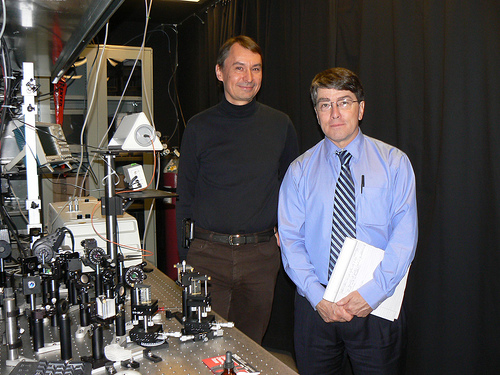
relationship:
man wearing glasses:
[277, 64, 419, 374] [309, 89, 356, 114]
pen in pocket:
[358, 174, 365, 191] [355, 184, 392, 229]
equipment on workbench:
[1, 0, 254, 371] [3, 255, 300, 374]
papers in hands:
[321, 237, 409, 322] [313, 288, 370, 324]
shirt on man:
[173, 86, 291, 291] [178, 36, 288, 340]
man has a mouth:
[277, 64, 419, 374] [314, 114, 355, 138]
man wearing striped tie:
[277, 64, 419, 374] [328, 148, 360, 278]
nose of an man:
[330, 105, 342, 119] [277, 64, 419, 374]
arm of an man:
[375, 152, 418, 294] [277, 64, 419, 374]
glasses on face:
[247, 74, 423, 366] [297, 71, 382, 146]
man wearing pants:
[171, 35, 285, 310] [182, 215, 275, 320]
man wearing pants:
[277, 64, 419, 374] [294, 283, 404, 373]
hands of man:
[311, 285, 371, 337] [277, 64, 419, 374]